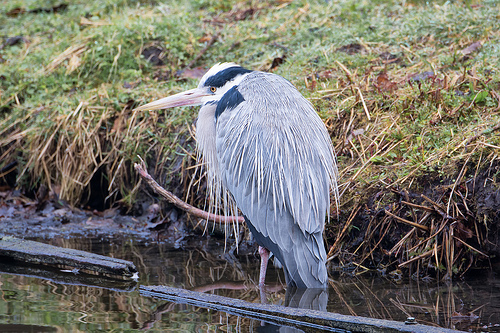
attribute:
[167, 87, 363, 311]
bird — standing, landed, looking, wanting, hiding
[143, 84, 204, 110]
beak — tan, pointed, long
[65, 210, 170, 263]
water — beside, calm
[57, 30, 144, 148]
grass — green, dried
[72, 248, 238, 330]
stick — lying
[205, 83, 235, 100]
eye — yellow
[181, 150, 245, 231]
feathers — white, gray, colorful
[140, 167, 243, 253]
leg — pink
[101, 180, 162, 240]
mud — beside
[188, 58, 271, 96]
stripe — black